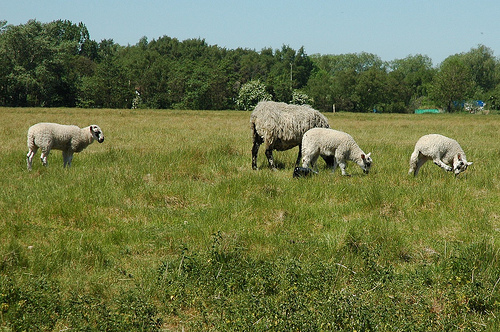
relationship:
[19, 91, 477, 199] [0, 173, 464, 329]
lambs feeding in field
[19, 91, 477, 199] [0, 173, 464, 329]
lambs grazing in field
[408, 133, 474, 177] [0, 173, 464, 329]
lamb grazing in field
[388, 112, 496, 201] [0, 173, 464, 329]
lamb grazing in field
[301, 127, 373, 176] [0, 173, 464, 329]
lamb grazing in field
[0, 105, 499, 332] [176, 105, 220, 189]
grass growing in ground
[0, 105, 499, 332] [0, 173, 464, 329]
grass growing in field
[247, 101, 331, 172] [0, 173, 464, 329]
lambs grazing in field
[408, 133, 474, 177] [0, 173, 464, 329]
lamb standing in field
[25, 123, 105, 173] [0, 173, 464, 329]
lamb standing in field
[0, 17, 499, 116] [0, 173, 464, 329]
trees growing in field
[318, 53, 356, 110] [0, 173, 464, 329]
trees growing in field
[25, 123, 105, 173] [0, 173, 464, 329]
lamb grazing in field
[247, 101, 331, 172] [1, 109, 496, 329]
lambs in field